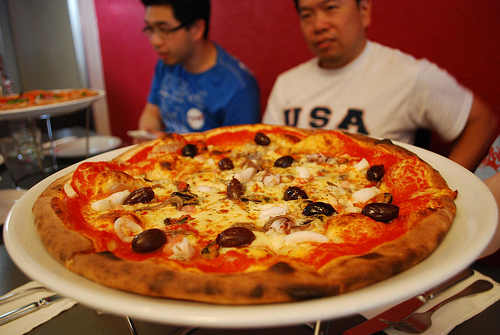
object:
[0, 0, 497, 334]
background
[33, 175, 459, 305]
crust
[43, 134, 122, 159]
plate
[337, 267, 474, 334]
silverware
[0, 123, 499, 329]
tray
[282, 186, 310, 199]
olve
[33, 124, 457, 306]
pizza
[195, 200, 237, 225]
cheese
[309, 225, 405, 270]
tomato sauce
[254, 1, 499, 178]
man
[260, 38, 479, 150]
shirt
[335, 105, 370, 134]
writing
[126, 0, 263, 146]
man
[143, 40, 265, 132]
shirt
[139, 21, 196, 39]
glasses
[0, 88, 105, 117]
pizza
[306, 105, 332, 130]
s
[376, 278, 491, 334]
fork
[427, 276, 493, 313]
handle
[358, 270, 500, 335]
napkin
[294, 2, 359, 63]
face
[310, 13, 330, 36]
nose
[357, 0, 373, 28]
ear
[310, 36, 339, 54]
mouth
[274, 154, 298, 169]
olive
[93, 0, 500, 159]
wall